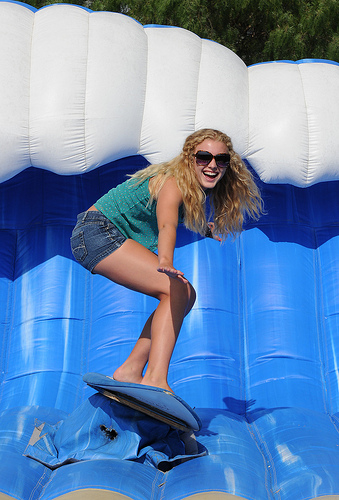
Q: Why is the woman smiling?
A: Because she is happy.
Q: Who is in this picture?
A: A woman.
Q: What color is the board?
A: Blue.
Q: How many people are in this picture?
A: One.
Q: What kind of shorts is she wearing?
A: Jean.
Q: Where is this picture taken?
A: Outside on an inflatable blow up toy.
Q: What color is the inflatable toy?
A: Blue and white.